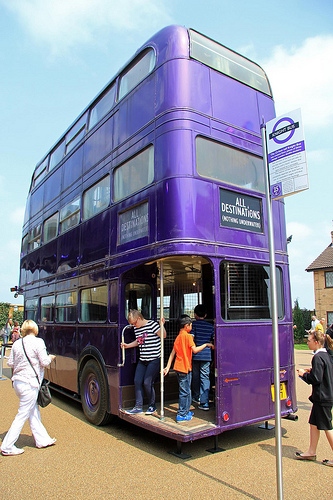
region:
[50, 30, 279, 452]
triple deck purple bus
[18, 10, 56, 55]
white clouds in blue sky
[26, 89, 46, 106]
white clouds in blue sky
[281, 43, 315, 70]
white clouds in blue sky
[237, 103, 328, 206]
bus stop sign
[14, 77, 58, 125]
white clouds in blue sky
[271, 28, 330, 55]
white clouds in blue sky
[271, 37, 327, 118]
white clouds in blue sky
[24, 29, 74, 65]
white clouds in blue sky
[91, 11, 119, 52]
white clouds in blue sky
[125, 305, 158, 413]
person wearing blue pants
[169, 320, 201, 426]
person wearing blue pants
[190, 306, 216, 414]
person wearing blue pants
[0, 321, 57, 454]
person wearing long pants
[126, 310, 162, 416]
person wearing long pants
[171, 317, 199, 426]
person wearing long pants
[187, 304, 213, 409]
person wearing long pants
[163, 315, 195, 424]
boy wearing orange short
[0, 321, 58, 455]
person wearing white pants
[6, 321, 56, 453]
person wearing white shirt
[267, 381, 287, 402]
yellow license plate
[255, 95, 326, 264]
sign post near the street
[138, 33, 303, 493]
purple triple level bus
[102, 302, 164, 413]
person getting off the bus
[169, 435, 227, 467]
metal bars under the bus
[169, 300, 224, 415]
children getting on the bus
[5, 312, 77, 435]
woman walking toward the bus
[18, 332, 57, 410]
woman with a messenger bag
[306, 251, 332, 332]
house behind the bus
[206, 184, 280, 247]
green sign on the bus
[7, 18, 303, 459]
shiny purple triple decker bus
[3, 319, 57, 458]
blonde lady wearing white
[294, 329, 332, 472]
girl wearing all black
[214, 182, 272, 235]
black and white sign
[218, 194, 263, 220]
white letters reading 'All Destinations'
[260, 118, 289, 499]
thin silver metal pole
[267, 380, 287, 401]
yellow and black license plate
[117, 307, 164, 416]
person in a black and white striped shirt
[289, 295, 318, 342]
tall ever green bushes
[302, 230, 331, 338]
two story tan brick building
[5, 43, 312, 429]
a bus on the road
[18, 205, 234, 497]
a passenger bus on the road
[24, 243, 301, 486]
a passenger bus on the street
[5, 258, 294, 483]
a purple bus on the road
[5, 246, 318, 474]
a purple bus on the street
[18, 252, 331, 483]
a purple passenger bus on the road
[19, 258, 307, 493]
a purple passenger bus on the street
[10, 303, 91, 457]
a purple passenger bus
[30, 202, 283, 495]
a tall purple bus